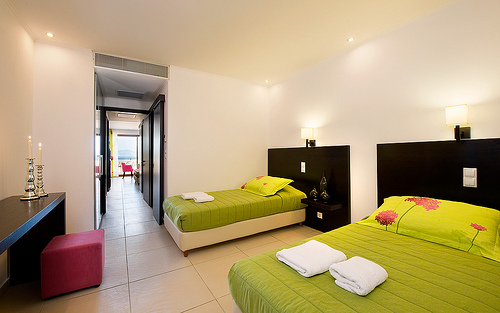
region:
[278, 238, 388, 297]
Two white towels are on the bed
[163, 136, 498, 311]
The room has two green beds.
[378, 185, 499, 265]
The pillow has flowers on it.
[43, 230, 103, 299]
A pink cube-shaped seat.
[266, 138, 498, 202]
The headstands are black.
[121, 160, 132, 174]
A red chair is down the hallway.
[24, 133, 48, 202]
Two candlesticks are on the desk.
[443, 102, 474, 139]
The light is turned on.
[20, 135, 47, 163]
The candles have been lit.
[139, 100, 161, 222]
Some black doors are down the hallway.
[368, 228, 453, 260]
the comforter is green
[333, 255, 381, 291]
the towels are white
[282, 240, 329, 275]
the towel is white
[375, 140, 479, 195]
the headboard is black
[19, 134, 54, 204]
the candles are lit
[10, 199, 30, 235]
the surface is black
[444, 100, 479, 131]
light is on the wall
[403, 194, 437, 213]
flowers are on the pillow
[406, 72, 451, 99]
light reflection is on the wall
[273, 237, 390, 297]
square white rolled up towels on bed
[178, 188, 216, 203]
square white rolled up towels on bed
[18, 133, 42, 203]
white candle in silver candleholder on table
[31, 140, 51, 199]
white candle in silver candleholder on table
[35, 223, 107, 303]
light red square ottoman near table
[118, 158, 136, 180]
red chair near window at the end of hall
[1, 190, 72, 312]
long narrow brown wooden table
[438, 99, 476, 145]
square white light on wall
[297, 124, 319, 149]
square white light on wall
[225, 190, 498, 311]
green rectangular bed against wall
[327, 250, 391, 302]
a white folded towel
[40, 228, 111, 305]
a square, pink ottoman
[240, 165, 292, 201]
a neon green pillowcase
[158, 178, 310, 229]
a simple green quilt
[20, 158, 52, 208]
a pair of candlesticks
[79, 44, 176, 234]
an empty hallway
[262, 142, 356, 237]
a wood headboard and shelf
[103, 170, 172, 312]
a white tile floor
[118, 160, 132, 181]
a bright pink chair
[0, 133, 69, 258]
two white lit candles on a black table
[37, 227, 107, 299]
empty square red seat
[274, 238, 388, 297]
two white folded towels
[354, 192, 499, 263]
red floral designs on a green pillow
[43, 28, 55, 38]
round white lit light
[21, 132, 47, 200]
lit candles in a silver holder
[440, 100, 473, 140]
lit white and black light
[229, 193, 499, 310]
white folded towels on a green bed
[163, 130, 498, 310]
two identical green beds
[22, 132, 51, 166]
two white lit candles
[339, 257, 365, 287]
a towel on the bed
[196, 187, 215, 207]
a towel on the bed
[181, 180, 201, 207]
a towel on the bed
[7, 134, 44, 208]
a candle on the desk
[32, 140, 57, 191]
a candle on the desk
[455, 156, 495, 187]
an electrical plug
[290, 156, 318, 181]
an electrical plug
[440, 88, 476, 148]
a light on the wall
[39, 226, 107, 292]
red ottoman by the table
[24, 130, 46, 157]
candles on the candlesticks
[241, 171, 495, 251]
pillows on the bed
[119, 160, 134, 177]
pink chair down the hallway